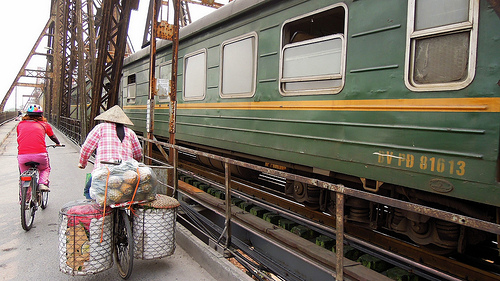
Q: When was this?
A: Daytime.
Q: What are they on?
A: Bikes.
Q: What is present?
A: A train.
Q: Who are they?
A: Citizens.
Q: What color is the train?
A: Green.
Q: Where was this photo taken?
A: On a bridge.